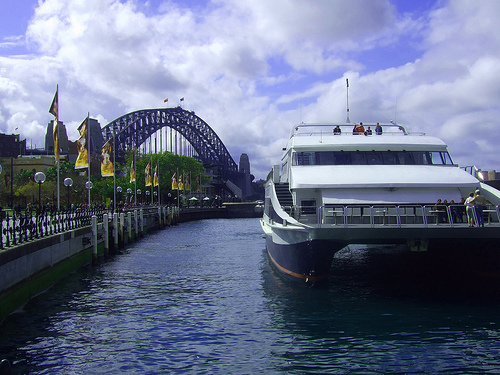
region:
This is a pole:
[49, 74, 76, 225]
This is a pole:
[78, 100, 105, 222]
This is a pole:
[108, 117, 125, 230]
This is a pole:
[129, 137, 144, 222]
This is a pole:
[148, 150, 156, 216]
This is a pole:
[175, 161, 182, 216]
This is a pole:
[180, 167, 187, 214]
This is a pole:
[188, 165, 193, 216]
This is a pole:
[197, 162, 209, 212]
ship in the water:
[263, 83, 484, 294]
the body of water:
[118, 266, 193, 359]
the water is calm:
[167, 330, 262, 356]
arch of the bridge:
[81, 114, 243, 187]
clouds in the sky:
[165, 12, 361, 99]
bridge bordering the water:
[32, 191, 198, 235]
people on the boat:
[324, 113, 393, 139]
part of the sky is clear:
[364, 18, 402, 64]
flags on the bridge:
[155, 93, 188, 105]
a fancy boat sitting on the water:
[254, 116, 499, 297]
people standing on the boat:
[331, 123, 388, 138]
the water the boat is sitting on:
[6, 206, 498, 371]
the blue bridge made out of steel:
[100, 109, 234, 167]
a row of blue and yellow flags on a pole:
[48, 85, 205, 194]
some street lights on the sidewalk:
[28, 169, 95, 209]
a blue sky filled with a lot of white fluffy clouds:
[4, 3, 496, 168]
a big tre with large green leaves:
[125, 151, 207, 191]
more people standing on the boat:
[428, 198, 485, 221]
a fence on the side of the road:
[2, 204, 124, 247]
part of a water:
[205, 291, 246, 351]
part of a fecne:
[325, 199, 343, 231]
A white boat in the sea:
[261, 77, 498, 282]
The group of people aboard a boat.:
[341, 121, 388, 134]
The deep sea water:
[0, 215, 498, 374]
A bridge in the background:
[82, 98, 242, 185]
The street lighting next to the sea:
[33, 170, 198, 209]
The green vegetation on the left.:
[0, 152, 207, 209]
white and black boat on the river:
[226, 95, 491, 327]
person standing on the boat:
[458, 180, 485, 222]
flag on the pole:
[42, 82, 70, 227]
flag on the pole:
[71, 110, 98, 227]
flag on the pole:
[96, 128, 119, 237]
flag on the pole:
[125, 146, 138, 231]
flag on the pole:
[142, 150, 152, 206]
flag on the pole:
[151, 158, 159, 210]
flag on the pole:
[166, 168, 177, 222]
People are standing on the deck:
[277, 93, 440, 165]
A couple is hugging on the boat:
[421, 153, 498, 258]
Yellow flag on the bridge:
[69, 108, 116, 275]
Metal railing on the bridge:
[8, 178, 247, 295]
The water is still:
[111, 254, 381, 370]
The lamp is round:
[23, 165, 55, 225]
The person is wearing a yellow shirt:
[470, 183, 490, 233]